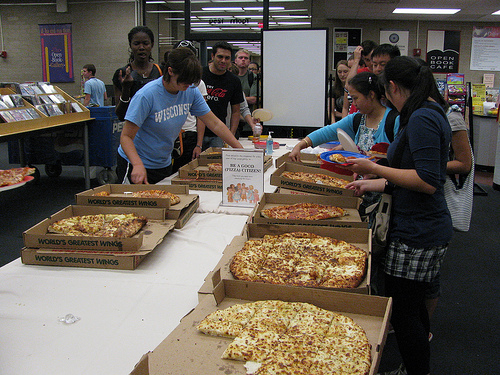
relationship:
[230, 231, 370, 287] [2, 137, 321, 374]
pizza on a table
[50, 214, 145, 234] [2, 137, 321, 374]
pizza on a table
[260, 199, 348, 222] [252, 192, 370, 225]
pizza in a box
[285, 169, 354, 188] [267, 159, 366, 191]
pizza in a box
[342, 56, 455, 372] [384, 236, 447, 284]
girl in skirt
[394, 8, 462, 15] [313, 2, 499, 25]
light on ceiling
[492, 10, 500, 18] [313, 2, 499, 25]
light on ceiling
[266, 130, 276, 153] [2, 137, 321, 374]
hand sanitizer on table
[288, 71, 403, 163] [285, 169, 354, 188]
person takes pizza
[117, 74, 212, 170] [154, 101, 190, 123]
shirt has lettering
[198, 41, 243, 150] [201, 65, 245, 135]
person wearing shirt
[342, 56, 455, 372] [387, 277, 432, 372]
girl wears leggings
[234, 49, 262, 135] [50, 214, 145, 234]
person buys pizza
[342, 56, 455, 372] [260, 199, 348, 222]
girl takes pizza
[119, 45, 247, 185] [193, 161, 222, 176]
woman serves pizza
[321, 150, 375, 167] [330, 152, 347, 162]
dish has slice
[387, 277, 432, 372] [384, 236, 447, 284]
leggings under skirt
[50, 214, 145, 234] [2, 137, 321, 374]
pizza on table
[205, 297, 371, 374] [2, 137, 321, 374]
pizza on table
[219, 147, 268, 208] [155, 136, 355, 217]
sign on table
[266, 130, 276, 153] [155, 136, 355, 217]
hand sanitizer on table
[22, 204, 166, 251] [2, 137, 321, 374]
box on top of table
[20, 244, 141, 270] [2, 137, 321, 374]
box on top of table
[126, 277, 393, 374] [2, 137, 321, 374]
box on top of table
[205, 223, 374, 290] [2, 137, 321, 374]
box on top of table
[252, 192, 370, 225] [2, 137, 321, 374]
box on top of table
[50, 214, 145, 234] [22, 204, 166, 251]
pizza sitting in box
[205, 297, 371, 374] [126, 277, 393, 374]
pizza sitting in box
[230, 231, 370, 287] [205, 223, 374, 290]
pizza sitting in box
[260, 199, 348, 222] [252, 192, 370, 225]
pizza sitting in box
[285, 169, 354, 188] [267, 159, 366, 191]
pizza sitting in box